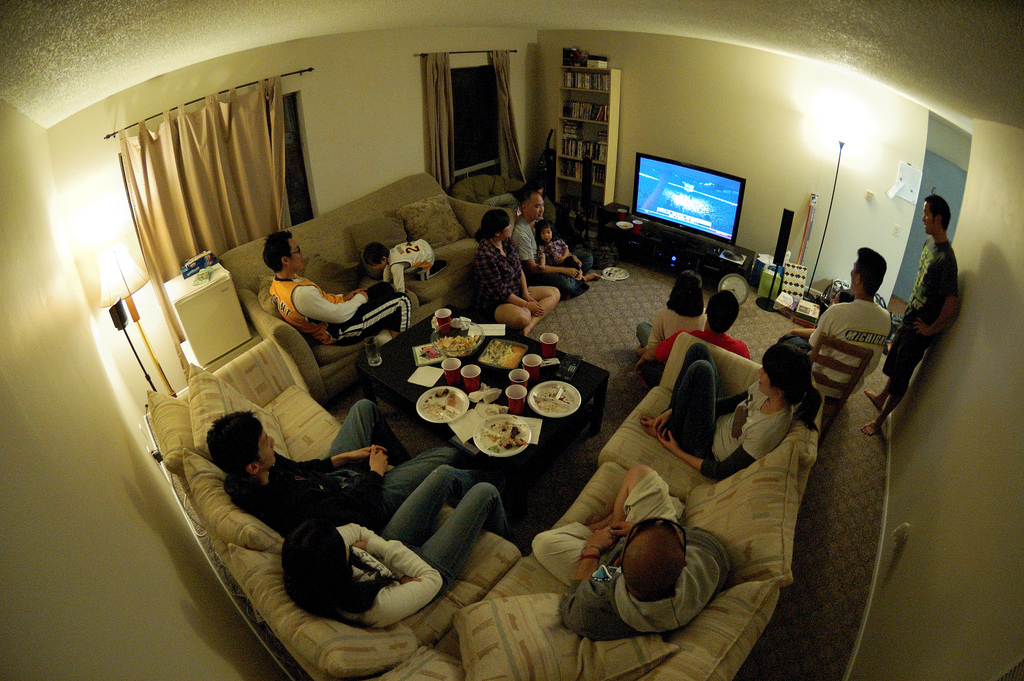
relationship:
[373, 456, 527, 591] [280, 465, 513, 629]
pants on female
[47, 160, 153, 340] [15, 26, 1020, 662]
light in room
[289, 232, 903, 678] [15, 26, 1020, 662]
rug in room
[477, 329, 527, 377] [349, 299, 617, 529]
food on table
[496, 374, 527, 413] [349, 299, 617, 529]
drink on table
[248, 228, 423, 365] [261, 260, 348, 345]
male wearing jersey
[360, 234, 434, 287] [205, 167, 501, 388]
child on couch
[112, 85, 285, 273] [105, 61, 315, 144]
curtain hanging from rod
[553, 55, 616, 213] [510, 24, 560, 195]
shelf in corner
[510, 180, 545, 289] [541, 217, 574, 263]
man holding girl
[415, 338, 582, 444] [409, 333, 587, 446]
cups with plates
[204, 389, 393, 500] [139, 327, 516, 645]
male sitting on a couch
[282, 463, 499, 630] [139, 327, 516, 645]
female sitting on a couch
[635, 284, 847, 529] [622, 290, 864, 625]
person sitting on sofa